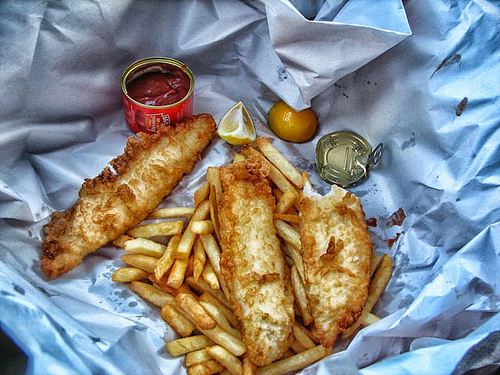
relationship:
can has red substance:
[120, 57, 195, 135] [128, 67, 185, 99]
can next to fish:
[90, 63, 227, 141] [63, 113, 250, 240]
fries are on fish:
[108, 138, 395, 373] [35, 110, 368, 356]